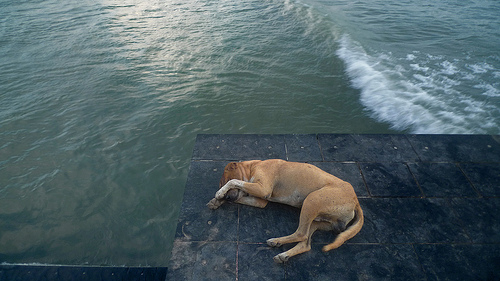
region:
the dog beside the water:
[207, 141, 369, 267]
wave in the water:
[327, 15, 464, 139]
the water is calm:
[22, 9, 315, 111]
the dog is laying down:
[204, 148, 384, 259]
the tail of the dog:
[316, 210, 369, 254]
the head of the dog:
[210, 157, 246, 202]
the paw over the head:
[216, 175, 247, 198]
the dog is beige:
[200, 149, 380, 269]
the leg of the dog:
[268, 188, 338, 247]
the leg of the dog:
[275, 214, 325, 266]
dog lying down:
[202, 153, 382, 261]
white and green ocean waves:
[7, 15, 64, 65]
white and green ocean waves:
[321, 23, 359, 48]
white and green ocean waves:
[417, 66, 468, 117]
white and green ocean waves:
[241, 15, 301, 82]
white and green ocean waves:
[88, 48, 129, 95]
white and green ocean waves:
[208, 61, 265, 93]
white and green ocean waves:
[81, 83, 129, 125]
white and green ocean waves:
[92, 135, 117, 179]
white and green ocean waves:
[34, 173, 88, 227]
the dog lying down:
[205, 155, 366, 262]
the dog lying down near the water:
[207, 158, 364, 262]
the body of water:
[0, 0, 497, 266]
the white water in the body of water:
[334, 27, 499, 134]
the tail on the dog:
[320, 204, 364, 251]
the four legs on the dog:
[207, 175, 332, 263]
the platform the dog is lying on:
[167, 133, 497, 279]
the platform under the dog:
[167, 132, 498, 279]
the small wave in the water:
[283, 0, 454, 136]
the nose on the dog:
[224, 193, 230, 200]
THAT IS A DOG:
[209, 153, 356, 268]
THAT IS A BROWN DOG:
[216, 159, 378, 246]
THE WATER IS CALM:
[89, 144, 121, 190]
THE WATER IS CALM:
[46, 150, 91, 214]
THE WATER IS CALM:
[53, 45, 100, 112]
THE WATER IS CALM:
[76, 62, 176, 107]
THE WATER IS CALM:
[123, 13, 215, 80]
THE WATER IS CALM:
[206, 41, 271, 117]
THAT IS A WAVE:
[359, 21, 470, 119]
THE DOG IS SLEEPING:
[216, 150, 370, 267]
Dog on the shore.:
[196, 140, 359, 254]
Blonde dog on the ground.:
[188, 133, 402, 271]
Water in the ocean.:
[95, 15, 216, 118]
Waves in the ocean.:
[266, 4, 388, 138]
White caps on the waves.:
[334, 9, 469, 153]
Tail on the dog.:
[310, 181, 375, 279]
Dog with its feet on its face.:
[201, 137, 279, 223]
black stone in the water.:
[309, 113, 488, 280]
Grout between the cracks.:
[353, 120, 478, 233]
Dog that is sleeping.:
[208, 142, 398, 268]